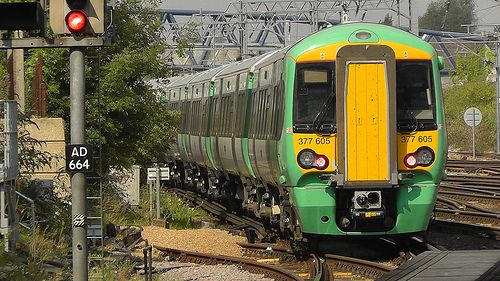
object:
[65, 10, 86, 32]
light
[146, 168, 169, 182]
sign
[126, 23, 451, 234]
train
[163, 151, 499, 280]
tracks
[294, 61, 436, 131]
windshield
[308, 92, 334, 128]
wiper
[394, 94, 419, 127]
wiper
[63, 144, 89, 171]
sign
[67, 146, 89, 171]
writing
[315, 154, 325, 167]
headlight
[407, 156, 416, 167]
headlight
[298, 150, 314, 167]
headlight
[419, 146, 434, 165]
headlight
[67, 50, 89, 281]
pole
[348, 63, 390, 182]
door